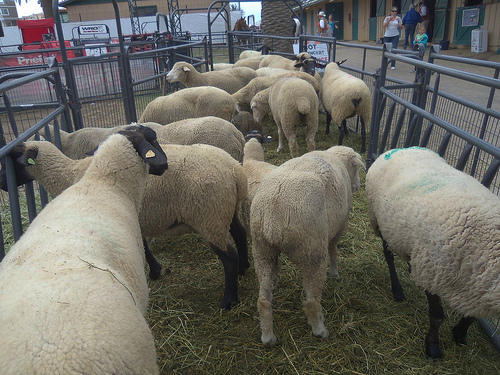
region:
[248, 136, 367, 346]
a standing white sheep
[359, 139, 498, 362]
a standing white sheep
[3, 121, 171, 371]
a standing white sheep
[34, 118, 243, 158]
a standing white sheep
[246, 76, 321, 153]
a standing white sheep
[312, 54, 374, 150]
a standing white sheep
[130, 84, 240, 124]
a grazing white sheep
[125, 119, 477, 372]
a floor a hay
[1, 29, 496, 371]
a metal sheep pen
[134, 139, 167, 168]
an identification marker on the sheep's ear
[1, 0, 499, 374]
an image of a sheep's pen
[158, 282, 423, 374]
the ground is covered in hay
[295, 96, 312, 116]
a stubby sheep's tail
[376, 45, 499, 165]
metal railing on the sheep's pen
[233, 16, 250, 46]
a brown horse on the outside of the sheep's pen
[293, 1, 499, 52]
beige and green horse stalls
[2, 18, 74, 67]
a red stage and booth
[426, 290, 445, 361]
a sheep's black legs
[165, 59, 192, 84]
a white faced sheep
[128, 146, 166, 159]
sheep has tag in ear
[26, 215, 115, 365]
sheep has wool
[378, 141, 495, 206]
aqua on the wool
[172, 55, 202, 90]
sheep ear is white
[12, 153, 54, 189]
the tag is green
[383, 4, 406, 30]
woman is wearing sunglasses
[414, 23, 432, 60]
kid's shirt is multi colored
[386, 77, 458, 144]
railing to sheep pen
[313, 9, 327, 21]
person is wearing cowboy hat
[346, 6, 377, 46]
two green doors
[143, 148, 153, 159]
yellow tag on sheep's ear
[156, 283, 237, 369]
trodden hay in fenced area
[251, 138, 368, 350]
all-cream sheep facing away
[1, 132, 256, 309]
black-and-white sheep with head through railings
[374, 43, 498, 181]
dark gray fencing containing sheep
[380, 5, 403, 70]
woman taking picture of sheep with phone camera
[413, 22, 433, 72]
child standing next to mother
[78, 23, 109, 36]
business sign reading "WRO" in large letters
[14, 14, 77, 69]
red and white plastic tarping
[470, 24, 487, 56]
white and black newspaper stand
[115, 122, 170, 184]
head of a sheep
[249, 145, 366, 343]
backside view of a sheep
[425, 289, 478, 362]
legs of a sheep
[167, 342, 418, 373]
hay on the ground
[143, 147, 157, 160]
marker on the ear of a sheep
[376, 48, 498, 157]
metal bars for a sheep pen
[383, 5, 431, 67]
woman and child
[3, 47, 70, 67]
red sign with white lettering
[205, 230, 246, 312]
leg of a sheep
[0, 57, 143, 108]
metal bars for a sheep pen